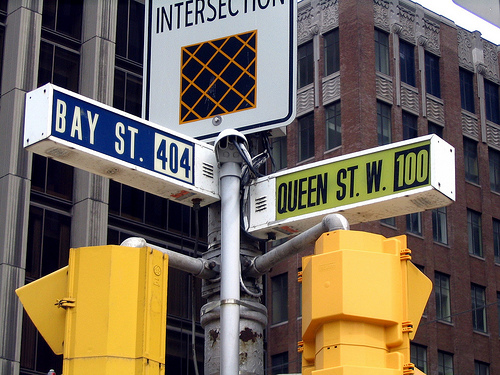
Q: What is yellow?
A: Traffic lights.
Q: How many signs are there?
A: Three.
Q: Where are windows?
A: On buildings.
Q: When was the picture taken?
A: Daytime.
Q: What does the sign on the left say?
A: "BAY ST.".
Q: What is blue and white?
A: Sign on left.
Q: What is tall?
A: The buildings.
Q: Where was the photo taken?
A: At corner of Queen St W.